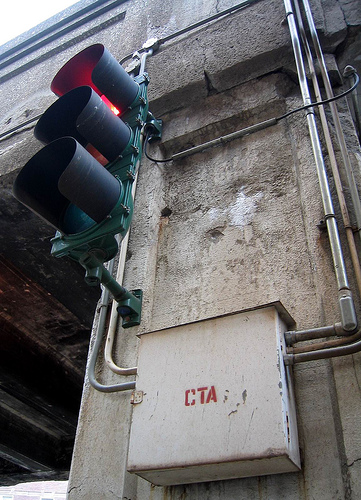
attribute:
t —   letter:
[196, 385, 206, 404]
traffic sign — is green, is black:
[11, 47, 162, 328]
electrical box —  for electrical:
[121, 287, 303, 490]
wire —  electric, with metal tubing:
[284, 5, 359, 252]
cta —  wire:
[158, 359, 229, 409]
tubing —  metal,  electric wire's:
[74, 275, 142, 395]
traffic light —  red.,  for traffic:
[50, 42, 143, 111]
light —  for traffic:
[19, 49, 149, 272]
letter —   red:
[180, 393, 195, 413]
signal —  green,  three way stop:
[15, 45, 165, 266]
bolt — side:
[119, 199, 131, 220]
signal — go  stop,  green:
[12, 137, 133, 229]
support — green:
[82, 251, 145, 330]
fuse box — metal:
[127, 300, 306, 487]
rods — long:
[291, 35, 341, 276]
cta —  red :
[181, 384, 216, 404]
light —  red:
[46, 36, 108, 89]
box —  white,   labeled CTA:
[120, 303, 305, 488]